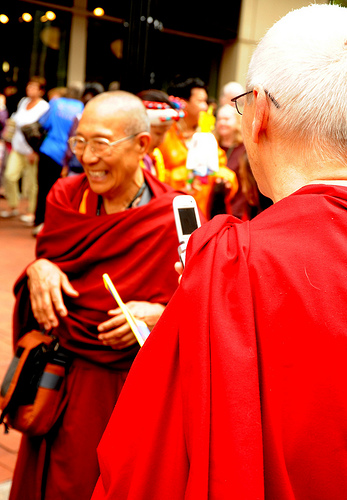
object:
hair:
[248, 5, 346, 147]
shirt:
[11, 99, 43, 154]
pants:
[33, 147, 63, 223]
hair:
[168, 74, 207, 103]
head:
[72, 88, 148, 193]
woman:
[3, 75, 43, 211]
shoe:
[0, 206, 15, 220]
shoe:
[18, 212, 35, 226]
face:
[66, 105, 118, 195]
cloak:
[91, 189, 344, 499]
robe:
[14, 170, 172, 499]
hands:
[16, 259, 170, 361]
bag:
[3, 320, 79, 435]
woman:
[217, 104, 244, 167]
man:
[43, 112, 181, 452]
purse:
[22, 122, 48, 149]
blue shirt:
[38, 96, 86, 164]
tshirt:
[37, 96, 83, 166]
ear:
[240, 89, 297, 139]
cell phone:
[173, 194, 201, 263]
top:
[171, 193, 201, 239]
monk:
[87, 3, 340, 498]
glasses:
[65, 131, 136, 153]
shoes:
[1, 209, 37, 223]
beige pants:
[5, 148, 37, 211]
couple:
[142, 73, 234, 234]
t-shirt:
[9, 96, 51, 155]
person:
[0, 73, 46, 212]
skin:
[68, 89, 152, 214]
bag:
[1, 120, 16, 143]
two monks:
[10, 49, 346, 473]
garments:
[40, 168, 346, 370]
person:
[30, 81, 84, 239]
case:
[0, 327, 74, 439]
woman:
[133, 87, 190, 182]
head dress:
[138, 93, 186, 129]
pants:
[3, 149, 37, 212]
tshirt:
[10, 97, 49, 153]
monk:
[8, 91, 203, 498]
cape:
[5, 154, 191, 489]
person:
[12, 80, 189, 498]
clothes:
[177, 131, 260, 217]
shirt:
[39, 98, 87, 164]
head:
[236, 3, 345, 194]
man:
[107, 0, 346, 498]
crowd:
[0, 6, 345, 491]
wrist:
[25, 257, 48, 272]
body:
[0, 89, 207, 498]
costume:
[159, 125, 234, 216]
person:
[2, 79, 46, 219]